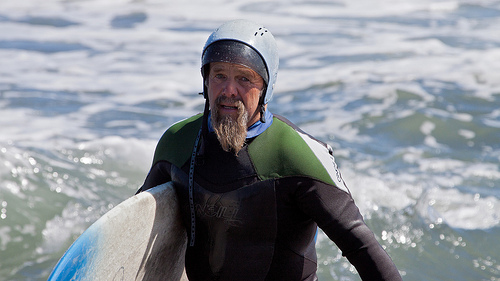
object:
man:
[139, 25, 402, 280]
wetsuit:
[132, 114, 401, 280]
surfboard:
[48, 179, 189, 281]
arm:
[139, 129, 168, 189]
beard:
[210, 110, 250, 158]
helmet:
[196, 18, 283, 105]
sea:
[1, 1, 496, 280]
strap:
[185, 113, 204, 248]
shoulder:
[153, 112, 202, 153]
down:
[192, 242, 193, 243]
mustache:
[213, 98, 250, 110]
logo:
[193, 198, 253, 221]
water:
[1, 1, 497, 280]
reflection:
[4, 151, 114, 204]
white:
[0, 0, 498, 165]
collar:
[207, 112, 275, 136]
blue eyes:
[237, 74, 258, 83]